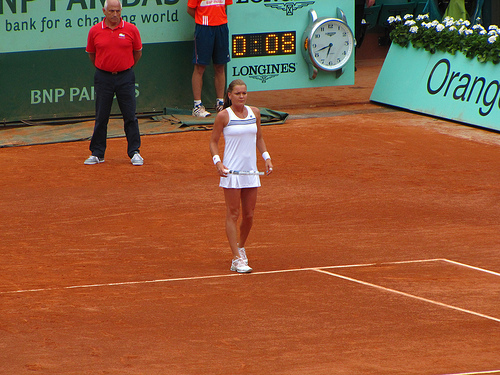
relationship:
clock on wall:
[231, 30, 295, 59] [226, 1, 355, 89]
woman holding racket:
[210, 80, 273, 273] [223, 169, 265, 176]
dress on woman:
[218, 106, 263, 189] [210, 80, 273, 273]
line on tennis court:
[310, 257, 445, 270] [5, 109, 497, 374]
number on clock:
[280, 33, 295, 53] [231, 30, 295, 59]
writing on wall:
[232, 62, 296, 76] [226, 1, 355, 89]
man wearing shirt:
[82, 0, 143, 166] [83, 16, 143, 74]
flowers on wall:
[387, 14, 499, 61] [368, 40, 499, 134]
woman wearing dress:
[210, 80, 273, 273] [218, 106, 263, 189]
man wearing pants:
[82, 0, 143, 166] [89, 68, 140, 156]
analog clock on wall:
[301, 8, 357, 80] [226, 1, 355, 89]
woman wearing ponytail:
[210, 80, 273, 273] [223, 80, 233, 109]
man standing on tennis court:
[82, 0, 143, 166] [5, 109, 497, 374]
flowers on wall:
[387, 14, 499, 61] [226, 1, 355, 89]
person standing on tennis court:
[186, 0, 231, 119] [5, 109, 497, 374]